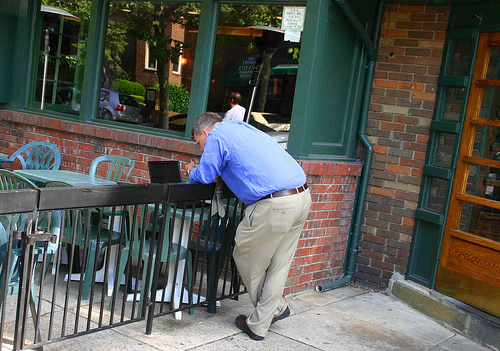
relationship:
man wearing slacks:
[188, 117, 309, 338] [239, 199, 300, 330]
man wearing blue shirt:
[188, 117, 309, 338] [197, 129, 300, 191]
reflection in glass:
[57, 15, 272, 123] [26, 3, 319, 137]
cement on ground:
[8, 270, 450, 349] [1, 269, 500, 350]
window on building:
[26, 3, 319, 137] [3, 2, 500, 274]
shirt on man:
[197, 129, 300, 191] [188, 117, 309, 338]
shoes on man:
[230, 313, 264, 341] [188, 117, 309, 338]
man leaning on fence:
[188, 117, 309, 338] [2, 190, 254, 329]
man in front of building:
[188, 117, 309, 338] [3, 2, 500, 274]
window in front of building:
[26, 3, 319, 137] [3, 2, 500, 274]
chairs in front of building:
[10, 145, 55, 215] [3, 2, 500, 274]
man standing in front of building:
[188, 117, 309, 338] [3, 2, 500, 274]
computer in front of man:
[148, 162, 205, 202] [188, 117, 309, 338]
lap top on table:
[148, 162, 205, 202] [145, 200, 234, 218]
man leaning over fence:
[188, 117, 309, 338] [2, 190, 254, 329]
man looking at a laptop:
[188, 117, 309, 338] [148, 162, 205, 202]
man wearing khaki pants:
[188, 117, 309, 338] [239, 199, 300, 330]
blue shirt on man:
[197, 129, 300, 191] [188, 117, 309, 338]